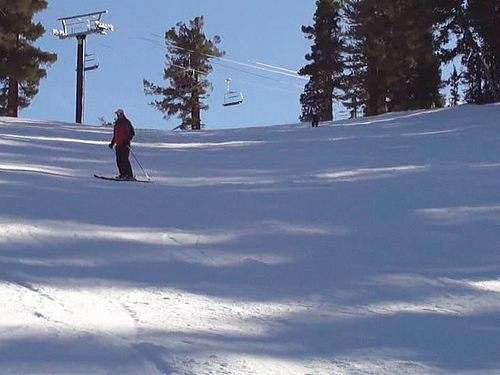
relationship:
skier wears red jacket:
[102, 98, 143, 194] [108, 115, 142, 150]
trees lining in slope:
[296, 3, 500, 127] [0, 103, 492, 368]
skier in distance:
[300, 95, 327, 131] [273, 72, 498, 135]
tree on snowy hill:
[142, 10, 237, 139] [0, 103, 492, 368]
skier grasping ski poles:
[102, 98, 143, 194] [108, 138, 156, 182]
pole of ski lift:
[49, 8, 105, 124] [36, 5, 307, 108]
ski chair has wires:
[221, 78, 244, 107] [106, 12, 320, 71]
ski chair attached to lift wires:
[221, 78, 244, 107] [106, 12, 320, 71]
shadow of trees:
[0, 98, 500, 375] [296, 3, 500, 127]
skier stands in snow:
[102, 98, 143, 194] [0, 103, 492, 368]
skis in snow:
[91, 168, 159, 189] [0, 103, 492, 368]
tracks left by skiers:
[15, 262, 382, 375] [89, 90, 163, 186]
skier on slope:
[102, 98, 143, 194] [0, 103, 492, 368]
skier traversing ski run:
[102, 98, 143, 194] [0, 103, 492, 368]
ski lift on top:
[36, 5, 307, 108] [3, 106, 495, 137]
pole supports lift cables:
[49, 8, 105, 124] [106, 12, 320, 71]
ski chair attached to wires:
[217, 85, 245, 112] [119, 28, 294, 72]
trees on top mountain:
[296, 3, 500, 127] [7, 84, 487, 126]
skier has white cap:
[102, 98, 143, 194] [111, 104, 128, 119]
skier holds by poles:
[102, 98, 143, 194] [46, 11, 366, 125]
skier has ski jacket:
[102, 98, 143, 194] [108, 115, 142, 150]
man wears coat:
[102, 98, 143, 194] [108, 115, 142, 150]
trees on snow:
[296, 3, 500, 127] [0, 103, 492, 368]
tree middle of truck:
[142, 10, 237, 139] [146, 110, 268, 195]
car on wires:
[217, 85, 245, 112] [106, 12, 320, 71]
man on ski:
[102, 98, 143, 194] [91, 168, 159, 189]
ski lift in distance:
[36, 5, 307, 108] [7, 84, 487, 126]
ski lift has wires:
[36, 5, 307, 108] [119, 28, 294, 72]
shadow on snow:
[0, 98, 500, 375] [0, 103, 492, 368]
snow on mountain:
[0, 103, 492, 368] [7, 84, 487, 126]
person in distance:
[300, 95, 327, 131] [273, 72, 498, 135]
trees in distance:
[296, 3, 500, 127] [273, 72, 498, 135]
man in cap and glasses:
[102, 98, 143, 194] [101, 107, 138, 161]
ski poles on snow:
[108, 138, 156, 182] [0, 103, 492, 368]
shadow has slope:
[0, 103, 492, 371] [0, 103, 492, 368]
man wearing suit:
[300, 95, 327, 131] [106, 110, 134, 175]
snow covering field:
[0, 103, 492, 368] [6, 99, 495, 371]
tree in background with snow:
[142, 10, 237, 139] [0, 103, 492, 368]